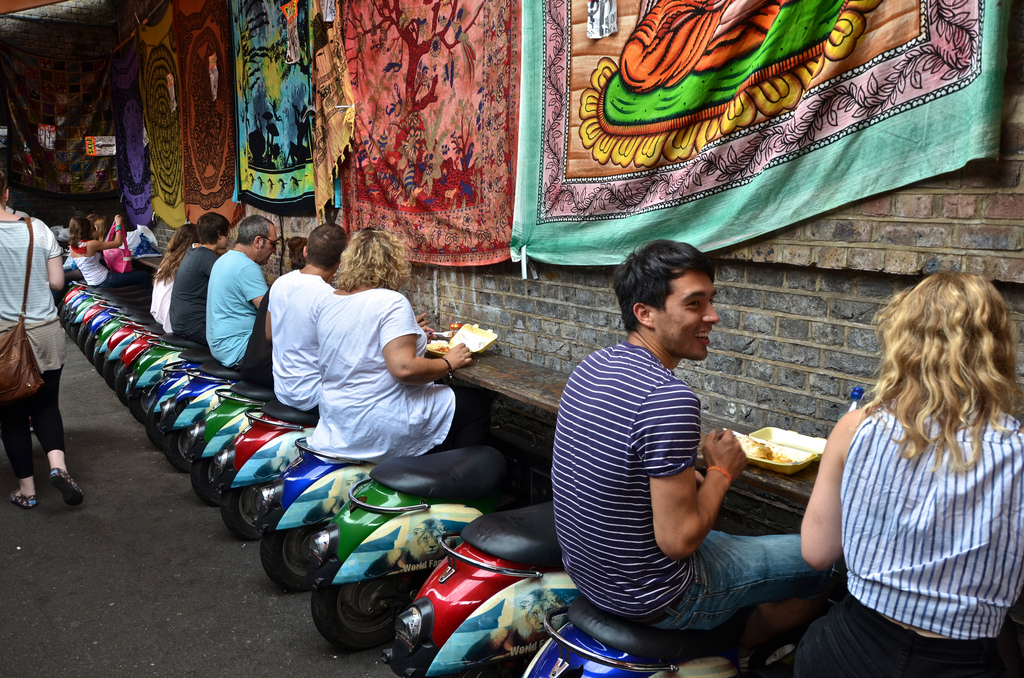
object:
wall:
[128, 3, 1024, 674]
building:
[0, 0, 1018, 673]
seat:
[460, 502, 559, 567]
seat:
[367, 444, 502, 500]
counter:
[121, 207, 1024, 516]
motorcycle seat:
[139, 357, 238, 458]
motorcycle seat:
[194, 405, 322, 539]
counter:
[266, 257, 913, 567]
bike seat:
[559, 586, 735, 675]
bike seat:
[384, 501, 565, 674]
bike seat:
[369, 441, 560, 656]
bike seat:
[262, 456, 371, 597]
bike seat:
[214, 412, 331, 548]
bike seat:
[150, 368, 278, 468]